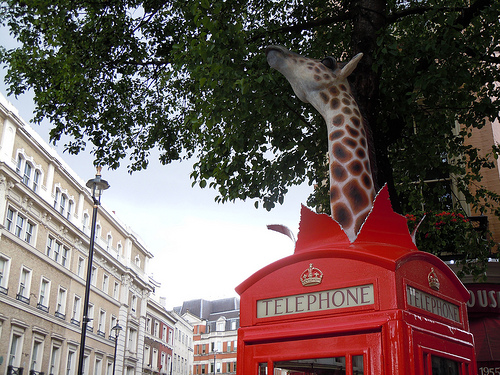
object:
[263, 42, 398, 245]
giraffe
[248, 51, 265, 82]
leaves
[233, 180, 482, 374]
cabin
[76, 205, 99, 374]
pole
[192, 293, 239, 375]
buildings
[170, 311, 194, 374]
buildings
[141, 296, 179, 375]
buildings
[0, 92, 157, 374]
buildings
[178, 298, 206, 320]
roof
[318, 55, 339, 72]
eye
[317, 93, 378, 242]
neck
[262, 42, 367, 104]
head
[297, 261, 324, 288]
crown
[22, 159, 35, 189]
windows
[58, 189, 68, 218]
windows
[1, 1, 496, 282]
tree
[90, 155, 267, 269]
sky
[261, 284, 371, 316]
telephone